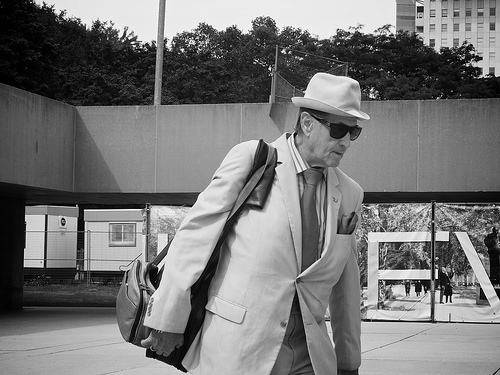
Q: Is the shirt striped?
A: Yes, the shirt is striped.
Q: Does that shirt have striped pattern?
A: Yes, the shirt is striped.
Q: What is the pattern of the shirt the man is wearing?
A: The shirt is striped.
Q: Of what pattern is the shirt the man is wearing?
A: The shirt is striped.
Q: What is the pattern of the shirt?
A: The shirt is striped.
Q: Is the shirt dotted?
A: No, the shirt is striped.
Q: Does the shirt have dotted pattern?
A: No, the shirt is striped.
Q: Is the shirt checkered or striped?
A: The shirt is striped.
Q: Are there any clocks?
A: No, there are no clocks.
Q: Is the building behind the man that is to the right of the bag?
A: Yes, the building is behind the man.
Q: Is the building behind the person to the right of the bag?
A: Yes, the building is behind the man.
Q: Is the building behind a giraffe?
A: No, the building is behind the man.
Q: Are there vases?
A: No, there are no vases.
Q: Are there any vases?
A: No, there are no vases.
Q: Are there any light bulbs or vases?
A: No, there are no vases or light bulbs.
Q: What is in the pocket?
A: The tissue is in the pocket.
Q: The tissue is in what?
A: The tissue is in the pocket.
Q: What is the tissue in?
A: The tissue is in the pocket.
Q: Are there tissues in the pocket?
A: Yes, there is a tissue in the pocket.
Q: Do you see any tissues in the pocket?
A: Yes, there is a tissue in the pocket.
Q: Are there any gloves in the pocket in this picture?
A: No, there is a tissue in the pocket.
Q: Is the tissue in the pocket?
A: Yes, the tissue is in the pocket.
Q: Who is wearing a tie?
A: The man is wearing a tie.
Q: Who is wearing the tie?
A: The man is wearing a tie.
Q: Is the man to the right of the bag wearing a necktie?
A: Yes, the man is wearing a necktie.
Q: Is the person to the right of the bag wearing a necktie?
A: Yes, the man is wearing a necktie.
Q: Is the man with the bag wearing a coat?
A: No, the man is wearing a necktie.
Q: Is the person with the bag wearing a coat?
A: No, the man is wearing a necktie.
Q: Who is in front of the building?
A: The man is in front of the building.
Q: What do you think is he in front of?
A: The man is in front of the building.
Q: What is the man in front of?
A: The man is in front of the building.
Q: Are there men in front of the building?
A: Yes, there is a man in front of the building.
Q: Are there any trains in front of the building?
A: No, there is a man in front of the building.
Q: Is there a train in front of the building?
A: No, there is a man in front of the building.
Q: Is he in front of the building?
A: Yes, the man is in front of the building.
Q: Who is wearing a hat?
A: The man is wearing a hat.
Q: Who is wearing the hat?
A: The man is wearing a hat.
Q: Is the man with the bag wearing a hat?
A: Yes, the man is wearing a hat.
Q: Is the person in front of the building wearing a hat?
A: Yes, the man is wearing a hat.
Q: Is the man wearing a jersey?
A: No, the man is wearing a hat.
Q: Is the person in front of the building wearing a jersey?
A: No, the man is wearing a hat.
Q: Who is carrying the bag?
A: The man is carrying the bag.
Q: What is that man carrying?
A: The man is carrying a bag.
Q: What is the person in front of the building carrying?
A: The man is carrying a bag.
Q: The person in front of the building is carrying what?
A: The man is carrying a bag.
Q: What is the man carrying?
A: The man is carrying a bag.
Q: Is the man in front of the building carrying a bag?
A: Yes, the man is carrying a bag.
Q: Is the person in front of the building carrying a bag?
A: Yes, the man is carrying a bag.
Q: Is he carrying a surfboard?
A: No, the man is carrying a bag.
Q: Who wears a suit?
A: The man wears a suit.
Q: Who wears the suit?
A: The man wears a suit.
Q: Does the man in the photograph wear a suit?
A: Yes, the man wears a suit.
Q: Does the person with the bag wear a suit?
A: Yes, the man wears a suit.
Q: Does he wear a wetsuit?
A: No, the man wears a suit.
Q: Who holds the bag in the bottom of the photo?
A: The man holds the bag.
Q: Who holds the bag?
A: The man holds the bag.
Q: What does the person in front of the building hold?
A: The man holds the bag.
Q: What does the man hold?
A: The man holds the bag.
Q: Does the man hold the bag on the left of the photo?
A: Yes, the man holds the bag.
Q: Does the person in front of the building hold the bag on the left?
A: Yes, the man holds the bag.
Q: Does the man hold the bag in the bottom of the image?
A: Yes, the man holds the bag.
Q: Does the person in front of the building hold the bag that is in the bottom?
A: Yes, the man holds the bag.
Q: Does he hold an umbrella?
A: No, the man holds the bag.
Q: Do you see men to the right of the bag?
A: Yes, there is a man to the right of the bag.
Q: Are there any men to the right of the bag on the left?
A: Yes, there is a man to the right of the bag.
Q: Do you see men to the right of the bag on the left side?
A: Yes, there is a man to the right of the bag.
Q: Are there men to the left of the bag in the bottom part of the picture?
A: No, the man is to the right of the bag.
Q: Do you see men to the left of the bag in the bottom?
A: No, the man is to the right of the bag.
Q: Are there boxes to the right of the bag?
A: No, there is a man to the right of the bag.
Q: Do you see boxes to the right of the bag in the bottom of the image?
A: No, there is a man to the right of the bag.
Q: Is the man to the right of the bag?
A: Yes, the man is to the right of the bag.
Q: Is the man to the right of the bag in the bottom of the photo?
A: Yes, the man is to the right of the bag.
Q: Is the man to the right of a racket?
A: No, the man is to the right of the bag.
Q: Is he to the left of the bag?
A: No, the man is to the right of the bag.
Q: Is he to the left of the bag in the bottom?
A: No, the man is to the right of the bag.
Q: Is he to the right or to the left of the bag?
A: The man is to the right of the bag.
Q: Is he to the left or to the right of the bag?
A: The man is to the right of the bag.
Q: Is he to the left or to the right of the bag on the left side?
A: The man is to the right of the bag.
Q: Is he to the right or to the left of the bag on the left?
A: The man is to the right of the bag.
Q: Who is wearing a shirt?
A: The man is wearing a shirt.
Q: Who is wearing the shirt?
A: The man is wearing a shirt.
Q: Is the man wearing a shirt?
A: Yes, the man is wearing a shirt.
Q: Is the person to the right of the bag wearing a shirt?
A: Yes, the man is wearing a shirt.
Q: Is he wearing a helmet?
A: No, the man is wearing a shirt.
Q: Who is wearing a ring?
A: The man is wearing a ring.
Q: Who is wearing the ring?
A: The man is wearing a ring.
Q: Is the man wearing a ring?
A: Yes, the man is wearing a ring.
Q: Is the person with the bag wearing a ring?
A: Yes, the man is wearing a ring.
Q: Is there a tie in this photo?
A: Yes, there is a tie.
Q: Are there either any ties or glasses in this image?
A: Yes, there is a tie.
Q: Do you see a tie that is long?
A: Yes, there is a long tie.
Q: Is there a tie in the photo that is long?
A: Yes, there is a tie that is long.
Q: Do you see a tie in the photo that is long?
A: Yes, there is a tie that is long.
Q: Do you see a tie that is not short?
A: Yes, there is a long tie.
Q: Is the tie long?
A: Yes, the tie is long.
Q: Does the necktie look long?
A: Yes, the necktie is long.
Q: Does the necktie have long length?
A: Yes, the necktie is long.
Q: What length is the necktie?
A: The necktie is long.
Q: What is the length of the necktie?
A: The necktie is long.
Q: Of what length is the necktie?
A: The necktie is long.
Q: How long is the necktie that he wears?
A: The necktie is long.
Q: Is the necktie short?
A: No, the necktie is long.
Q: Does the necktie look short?
A: No, the necktie is long.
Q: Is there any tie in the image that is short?
A: No, there is a tie but it is long.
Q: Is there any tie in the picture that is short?
A: No, there is a tie but it is long.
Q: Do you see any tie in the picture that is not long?
A: No, there is a tie but it is long.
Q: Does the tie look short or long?
A: The tie is long.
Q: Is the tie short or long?
A: The tie is long.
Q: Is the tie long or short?
A: The tie is long.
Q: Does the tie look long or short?
A: The tie is long.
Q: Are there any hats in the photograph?
A: Yes, there is a hat.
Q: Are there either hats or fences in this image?
A: Yes, there is a hat.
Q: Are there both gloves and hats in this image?
A: No, there is a hat but no gloves.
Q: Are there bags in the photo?
A: Yes, there is a bag.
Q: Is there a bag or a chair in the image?
A: Yes, there is a bag.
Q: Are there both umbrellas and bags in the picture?
A: No, there is a bag but no umbrellas.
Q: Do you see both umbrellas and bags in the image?
A: No, there is a bag but no umbrellas.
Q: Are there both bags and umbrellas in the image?
A: No, there is a bag but no umbrellas.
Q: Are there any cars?
A: No, there are no cars.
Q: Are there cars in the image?
A: No, there are no cars.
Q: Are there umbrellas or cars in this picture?
A: No, there are no cars or umbrellas.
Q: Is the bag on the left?
A: Yes, the bag is on the left of the image.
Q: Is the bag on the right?
A: No, the bag is on the left of the image.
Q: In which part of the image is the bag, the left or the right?
A: The bag is on the left of the image.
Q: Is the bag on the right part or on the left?
A: The bag is on the left of the image.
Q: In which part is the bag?
A: The bag is on the left of the image.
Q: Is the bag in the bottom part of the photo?
A: Yes, the bag is in the bottom of the image.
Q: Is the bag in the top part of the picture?
A: No, the bag is in the bottom of the image.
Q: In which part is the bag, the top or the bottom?
A: The bag is in the bottom of the image.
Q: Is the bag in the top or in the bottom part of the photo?
A: The bag is in the bottom of the image.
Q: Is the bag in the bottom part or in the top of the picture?
A: The bag is in the bottom of the image.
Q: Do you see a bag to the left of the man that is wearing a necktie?
A: Yes, there is a bag to the left of the man.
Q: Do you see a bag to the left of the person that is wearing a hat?
A: Yes, there is a bag to the left of the man.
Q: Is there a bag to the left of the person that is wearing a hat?
A: Yes, there is a bag to the left of the man.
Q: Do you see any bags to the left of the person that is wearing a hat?
A: Yes, there is a bag to the left of the man.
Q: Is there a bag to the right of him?
A: No, the bag is to the left of the man.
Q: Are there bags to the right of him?
A: No, the bag is to the left of the man.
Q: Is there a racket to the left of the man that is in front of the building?
A: No, there is a bag to the left of the man.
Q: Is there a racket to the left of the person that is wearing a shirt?
A: No, there is a bag to the left of the man.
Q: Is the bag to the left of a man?
A: Yes, the bag is to the left of a man.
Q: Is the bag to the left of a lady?
A: No, the bag is to the left of a man.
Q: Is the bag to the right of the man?
A: No, the bag is to the left of the man.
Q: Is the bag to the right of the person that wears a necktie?
A: No, the bag is to the left of the man.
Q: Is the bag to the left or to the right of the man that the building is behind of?
A: The bag is to the left of the man.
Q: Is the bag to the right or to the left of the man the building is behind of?
A: The bag is to the left of the man.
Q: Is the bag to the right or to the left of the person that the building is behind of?
A: The bag is to the left of the man.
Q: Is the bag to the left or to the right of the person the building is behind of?
A: The bag is to the left of the man.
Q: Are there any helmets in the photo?
A: No, there are no helmets.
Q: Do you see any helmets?
A: No, there are no helmets.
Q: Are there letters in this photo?
A: Yes, there are letters.